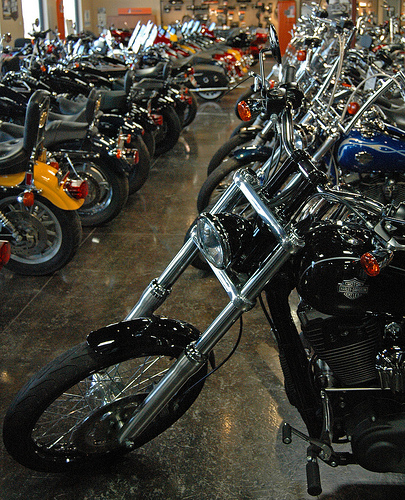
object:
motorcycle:
[0, 87, 89, 276]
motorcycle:
[0, 89, 132, 229]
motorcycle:
[171, 53, 232, 102]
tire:
[4, 340, 209, 479]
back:
[227, 44, 249, 74]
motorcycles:
[0, 0, 280, 305]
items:
[161, 0, 275, 38]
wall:
[81, 1, 328, 58]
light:
[68, 178, 89, 200]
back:
[34, 159, 91, 214]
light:
[240, 60, 251, 70]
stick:
[280, 420, 337, 468]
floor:
[0, 50, 404, 500]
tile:
[11, 264, 179, 325]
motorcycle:
[194, 22, 405, 211]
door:
[278, 0, 298, 60]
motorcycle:
[223, 39, 250, 77]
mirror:
[300, 0, 351, 21]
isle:
[0, 53, 284, 412]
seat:
[40, 120, 93, 149]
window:
[20, 0, 45, 42]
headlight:
[196, 212, 248, 269]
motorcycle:
[2, 0, 402, 495]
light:
[236, 100, 251, 123]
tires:
[2, 79, 200, 277]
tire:
[0, 188, 83, 278]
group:
[0, 3, 405, 500]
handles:
[308, 12, 347, 36]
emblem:
[337, 276, 369, 301]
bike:
[249, 33, 270, 57]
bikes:
[0, 1, 404, 88]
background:
[0, 0, 403, 155]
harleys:
[25, 38, 199, 131]